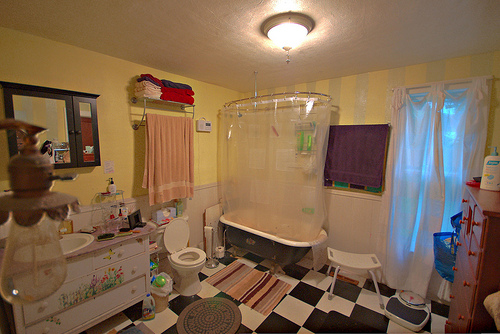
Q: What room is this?
A: It is a bathroom.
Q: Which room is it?
A: It is a bathroom.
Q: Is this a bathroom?
A: Yes, it is a bathroom.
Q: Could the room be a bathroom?
A: Yes, it is a bathroom.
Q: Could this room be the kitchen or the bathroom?
A: It is the bathroom.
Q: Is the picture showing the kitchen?
A: No, the picture is showing the bathroom.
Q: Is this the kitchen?
A: No, it is the bathroom.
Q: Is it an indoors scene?
A: Yes, it is indoors.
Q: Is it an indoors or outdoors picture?
A: It is indoors.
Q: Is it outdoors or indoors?
A: It is indoors.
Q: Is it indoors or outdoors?
A: It is indoors.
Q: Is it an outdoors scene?
A: No, it is indoors.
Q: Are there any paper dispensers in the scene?
A: No, there are no paper dispensers.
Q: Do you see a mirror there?
A: Yes, there is a mirror.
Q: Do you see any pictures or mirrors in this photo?
A: Yes, there is a mirror.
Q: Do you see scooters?
A: No, there are no scooters.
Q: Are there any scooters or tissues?
A: No, there are no scooters or tissues.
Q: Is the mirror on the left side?
A: Yes, the mirror is on the left of the image.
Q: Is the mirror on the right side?
A: No, the mirror is on the left of the image.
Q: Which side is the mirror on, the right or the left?
A: The mirror is on the left of the image.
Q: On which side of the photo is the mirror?
A: The mirror is on the left of the image.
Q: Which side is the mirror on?
A: The mirror is on the left of the image.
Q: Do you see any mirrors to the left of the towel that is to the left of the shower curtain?
A: Yes, there is a mirror to the left of the towel.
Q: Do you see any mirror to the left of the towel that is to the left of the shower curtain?
A: Yes, there is a mirror to the left of the towel.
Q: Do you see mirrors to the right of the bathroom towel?
A: No, the mirror is to the left of the towel.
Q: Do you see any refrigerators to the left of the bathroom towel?
A: No, there is a mirror to the left of the towel.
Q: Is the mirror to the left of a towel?
A: Yes, the mirror is to the left of a towel.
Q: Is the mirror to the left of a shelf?
A: No, the mirror is to the left of a towel.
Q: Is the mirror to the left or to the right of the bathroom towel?
A: The mirror is to the left of the towel.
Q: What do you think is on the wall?
A: The mirror is on the wall.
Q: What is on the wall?
A: The mirror is on the wall.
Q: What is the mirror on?
A: The mirror is on the wall.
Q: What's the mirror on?
A: The mirror is on the wall.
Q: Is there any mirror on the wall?
A: Yes, there is a mirror on the wall.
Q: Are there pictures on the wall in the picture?
A: No, there is a mirror on the wall.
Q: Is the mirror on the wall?
A: Yes, the mirror is on the wall.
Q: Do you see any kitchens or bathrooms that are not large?
A: No, there is a bathroom but it is large.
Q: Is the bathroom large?
A: Yes, the bathroom is large.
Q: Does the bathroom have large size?
A: Yes, the bathroom is large.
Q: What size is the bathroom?
A: The bathroom is large.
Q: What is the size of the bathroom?
A: The bathroom is large.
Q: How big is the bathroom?
A: The bathroom is large.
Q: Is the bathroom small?
A: No, the bathroom is large.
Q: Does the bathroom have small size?
A: No, the bathroom is large.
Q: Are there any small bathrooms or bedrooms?
A: No, there is a bathroom but it is large.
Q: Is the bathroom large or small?
A: The bathroom is large.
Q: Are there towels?
A: Yes, there is a towel.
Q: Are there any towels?
A: Yes, there is a towel.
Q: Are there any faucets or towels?
A: Yes, there is a towel.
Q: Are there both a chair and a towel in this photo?
A: Yes, there are both a towel and a chair.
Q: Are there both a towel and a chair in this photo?
A: Yes, there are both a towel and a chair.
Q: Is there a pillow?
A: No, there are no pillows.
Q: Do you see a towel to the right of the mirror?
A: Yes, there is a towel to the right of the mirror.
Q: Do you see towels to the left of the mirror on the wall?
A: No, the towel is to the right of the mirror.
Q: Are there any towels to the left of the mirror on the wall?
A: No, the towel is to the right of the mirror.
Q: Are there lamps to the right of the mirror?
A: No, there is a towel to the right of the mirror.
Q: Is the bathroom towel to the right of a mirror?
A: Yes, the towel is to the right of a mirror.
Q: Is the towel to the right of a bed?
A: No, the towel is to the right of a mirror.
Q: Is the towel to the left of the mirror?
A: No, the towel is to the right of the mirror.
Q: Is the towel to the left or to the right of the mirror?
A: The towel is to the right of the mirror.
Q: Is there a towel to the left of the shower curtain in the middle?
A: Yes, there is a towel to the left of the shower curtain.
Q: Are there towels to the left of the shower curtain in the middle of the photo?
A: Yes, there is a towel to the left of the shower curtain.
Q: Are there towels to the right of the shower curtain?
A: No, the towel is to the left of the shower curtain.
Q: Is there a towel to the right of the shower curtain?
A: No, the towel is to the left of the shower curtain.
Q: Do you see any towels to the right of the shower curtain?
A: No, the towel is to the left of the shower curtain.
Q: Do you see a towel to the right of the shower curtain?
A: No, the towel is to the left of the shower curtain.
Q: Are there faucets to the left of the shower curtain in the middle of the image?
A: No, there is a towel to the left of the shower curtain.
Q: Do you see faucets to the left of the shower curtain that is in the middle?
A: No, there is a towel to the left of the shower curtain.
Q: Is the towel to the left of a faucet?
A: No, the towel is to the left of the shower curtain.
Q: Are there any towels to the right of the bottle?
A: Yes, there is a towel to the right of the bottle.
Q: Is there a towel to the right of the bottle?
A: Yes, there is a towel to the right of the bottle.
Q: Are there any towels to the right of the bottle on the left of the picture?
A: Yes, there is a towel to the right of the bottle.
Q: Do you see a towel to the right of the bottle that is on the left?
A: Yes, there is a towel to the right of the bottle.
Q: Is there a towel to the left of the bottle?
A: No, the towel is to the right of the bottle.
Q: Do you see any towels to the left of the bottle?
A: No, the towel is to the right of the bottle.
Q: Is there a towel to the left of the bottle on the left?
A: No, the towel is to the right of the bottle.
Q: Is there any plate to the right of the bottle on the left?
A: No, there is a towel to the right of the bottle.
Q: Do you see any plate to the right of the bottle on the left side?
A: No, there is a towel to the right of the bottle.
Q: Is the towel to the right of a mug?
A: No, the towel is to the right of the bottle.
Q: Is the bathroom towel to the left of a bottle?
A: No, the towel is to the right of a bottle.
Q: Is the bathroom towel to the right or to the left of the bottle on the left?
A: The towel is to the right of the bottle.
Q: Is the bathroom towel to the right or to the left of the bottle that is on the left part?
A: The towel is to the right of the bottle.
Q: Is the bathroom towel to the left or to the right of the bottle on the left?
A: The towel is to the right of the bottle.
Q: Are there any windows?
A: Yes, there is a window.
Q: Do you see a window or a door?
A: Yes, there is a window.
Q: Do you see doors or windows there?
A: Yes, there is a window.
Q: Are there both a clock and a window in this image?
A: No, there is a window but no clocks.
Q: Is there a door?
A: No, there are no doors.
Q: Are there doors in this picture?
A: No, there are no doors.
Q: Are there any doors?
A: No, there are no doors.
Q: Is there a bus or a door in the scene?
A: No, there are no doors or buses.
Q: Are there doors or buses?
A: No, there are no doors or buses.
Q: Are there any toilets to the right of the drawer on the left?
A: Yes, there is a toilet to the right of the drawer.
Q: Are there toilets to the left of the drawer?
A: No, the toilet is to the right of the drawer.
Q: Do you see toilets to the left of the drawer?
A: No, the toilet is to the right of the drawer.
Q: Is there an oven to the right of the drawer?
A: No, there is a toilet to the right of the drawer.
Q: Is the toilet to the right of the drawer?
A: Yes, the toilet is to the right of the drawer.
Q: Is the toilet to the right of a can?
A: No, the toilet is to the right of the drawer.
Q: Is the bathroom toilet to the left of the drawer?
A: No, the toilet is to the right of the drawer.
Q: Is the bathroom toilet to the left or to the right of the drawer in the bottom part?
A: The toilet is to the right of the drawer.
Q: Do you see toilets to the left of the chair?
A: Yes, there is a toilet to the left of the chair.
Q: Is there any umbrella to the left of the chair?
A: No, there is a toilet to the left of the chair.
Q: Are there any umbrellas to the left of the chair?
A: No, there is a toilet to the left of the chair.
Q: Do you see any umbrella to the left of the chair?
A: No, there is a toilet to the left of the chair.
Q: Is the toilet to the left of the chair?
A: Yes, the toilet is to the left of the chair.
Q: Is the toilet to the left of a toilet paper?
A: No, the toilet is to the left of the chair.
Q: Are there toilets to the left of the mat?
A: Yes, there is a toilet to the left of the mat.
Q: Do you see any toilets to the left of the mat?
A: Yes, there is a toilet to the left of the mat.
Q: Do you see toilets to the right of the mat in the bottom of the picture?
A: No, the toilet is to the left of the mat.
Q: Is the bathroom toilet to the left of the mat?
A: Yes, the toilet is to the left of the mat.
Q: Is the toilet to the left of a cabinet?
A: No, the toilet is to the left of the mat.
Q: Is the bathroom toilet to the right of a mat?
A: No, the toilet is to the left of a mat.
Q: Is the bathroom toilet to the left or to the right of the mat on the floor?
A: The toilet is to the left of the mat.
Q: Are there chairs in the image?
A: Yes, there is a chair.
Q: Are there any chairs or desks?
A: Yes, there is a chair.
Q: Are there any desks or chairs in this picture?
A: Yes, there is a chair.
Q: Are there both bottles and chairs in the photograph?
A: Yes, there are both a chair and a bottle.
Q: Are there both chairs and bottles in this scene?
A: Yes, there are both a chair and a bottle.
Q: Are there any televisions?
A: No, there are no televisions.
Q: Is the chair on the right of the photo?
A: Yes, the chair is on the right of the image.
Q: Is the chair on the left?
A: No, the chair is on the right of the image.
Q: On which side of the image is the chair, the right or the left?
A: The chair is on the right of the image.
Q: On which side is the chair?
A: The chair is on the right of the image.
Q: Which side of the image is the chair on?
A: The chair is on the right of the image.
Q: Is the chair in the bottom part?
A: Yes, the chair is in the bottom of the image.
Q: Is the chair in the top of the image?
A: No, the chair is in the bottom of the image.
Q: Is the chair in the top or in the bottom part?
A: The chair is in the bottom of the image.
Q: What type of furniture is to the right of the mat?
A: The piece of furniture is a chair.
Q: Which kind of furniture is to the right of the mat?
A: The piece of furniture is a chair.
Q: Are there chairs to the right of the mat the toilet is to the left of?
A: Yes, there is a chair to the right of the mat.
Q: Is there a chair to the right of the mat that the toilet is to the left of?
A: Yes, there is a chair to the right of the mat.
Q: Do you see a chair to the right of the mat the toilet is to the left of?
A: Yes, there is a chair to the right of the mat.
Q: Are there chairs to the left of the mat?
A: No, the chair is to the right of the mat.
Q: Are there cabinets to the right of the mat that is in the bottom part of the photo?
A: No, there is a chair to the right of the mat.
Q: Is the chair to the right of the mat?
A: Yes, the chair is to the right of the mat.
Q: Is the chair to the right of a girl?
A: No, the chair is to the right of the mat.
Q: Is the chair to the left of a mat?
A: No, the chair is to the right of a mat.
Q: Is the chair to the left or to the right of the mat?
A: The chair is to the right of the mat.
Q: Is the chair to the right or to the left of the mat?
A: The chair is to the right of the mat.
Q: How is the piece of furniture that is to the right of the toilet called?
A: The piece of furniture is a chair.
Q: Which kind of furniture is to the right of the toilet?
A: The piece of furniture is a chair.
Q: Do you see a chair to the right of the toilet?
A: Yes, there is a chair to the right of the toilet.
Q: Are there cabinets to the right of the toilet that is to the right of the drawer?
A: No, there is a chair to the right of the toilet.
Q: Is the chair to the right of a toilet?
A: Yes, the chair is to the right of a toilet.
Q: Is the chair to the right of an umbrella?
A: No, the chair is to the right of a toilet.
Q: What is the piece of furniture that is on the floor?
A: The piece of furniture is a chair.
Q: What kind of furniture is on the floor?
A: The piece of furniture is a chair.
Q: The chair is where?
A: The chair is on the floor.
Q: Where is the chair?
A: The chair is on the floor.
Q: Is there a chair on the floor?
A: Yes, there is a chair on the floor.